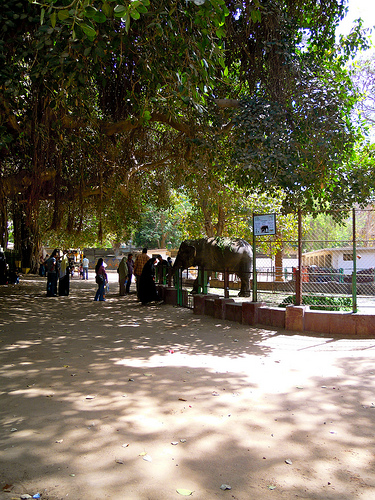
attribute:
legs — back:
[238, 269, 252, 296]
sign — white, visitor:
[251, 210, 276, 237]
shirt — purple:
[89, 265, 110, 282]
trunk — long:
[163, 260, 180, 281]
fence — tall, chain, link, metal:
[250, 206, 373, 315]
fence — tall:
[274, 212, 356, 294]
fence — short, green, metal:
[170, 264, 277, 310]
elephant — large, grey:
[163, 229, 259, 304]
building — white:
[301, 200, 373, 278]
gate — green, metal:
[174, 268, 209, 311]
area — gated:
[4, 191, 372, 496]